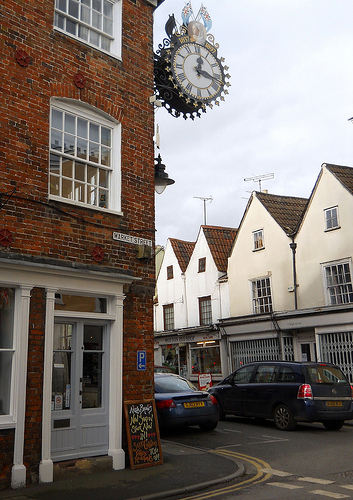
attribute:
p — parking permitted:
[138, 353, 145, 362]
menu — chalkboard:
[125, 401, 161, 462]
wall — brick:
[0, 1, 155, 479]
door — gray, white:
[52, 310, 110, 461]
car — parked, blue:
[154, 372, 219, 432]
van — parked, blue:
[206, 361, 353, 432]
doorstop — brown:
[52, 455, 112, 476]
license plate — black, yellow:
[182, 401, 208, 409]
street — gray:
[166, 411, 352, 497]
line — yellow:
[159, 451, 267, 496]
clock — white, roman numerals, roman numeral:
[151, 33, 228, 123]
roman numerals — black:
[171, 45, 222, 100]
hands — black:
[195, 54, 224, 83]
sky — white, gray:
[152, 0, 353, 248]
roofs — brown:
[227, 193, 306, 257]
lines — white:
[260, 462, 352, 500]